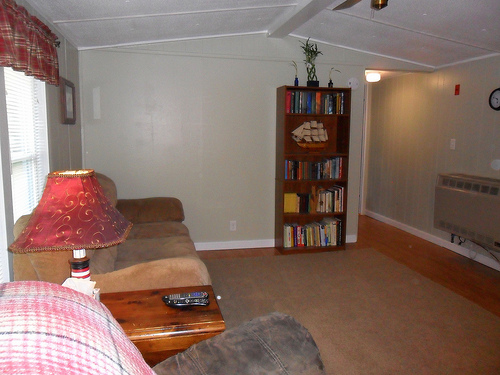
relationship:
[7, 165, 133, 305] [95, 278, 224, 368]
lamp on table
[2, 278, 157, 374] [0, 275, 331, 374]
blanket on chair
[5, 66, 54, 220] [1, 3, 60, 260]
blinds on window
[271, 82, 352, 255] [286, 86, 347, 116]
bookshelf has books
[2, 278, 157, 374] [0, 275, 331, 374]
afghan on chair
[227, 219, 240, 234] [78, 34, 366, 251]
outlet on wall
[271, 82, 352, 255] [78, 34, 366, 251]
bookshelf against wall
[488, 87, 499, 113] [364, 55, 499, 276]
clock on wall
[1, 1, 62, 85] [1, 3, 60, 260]
valance over window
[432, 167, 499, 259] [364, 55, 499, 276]
heater on wall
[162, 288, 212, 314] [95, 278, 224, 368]
remote controls on table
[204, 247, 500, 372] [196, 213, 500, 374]
rug on floor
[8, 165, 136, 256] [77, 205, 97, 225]
lampshade has swirls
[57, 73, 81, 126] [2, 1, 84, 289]
picture on wall